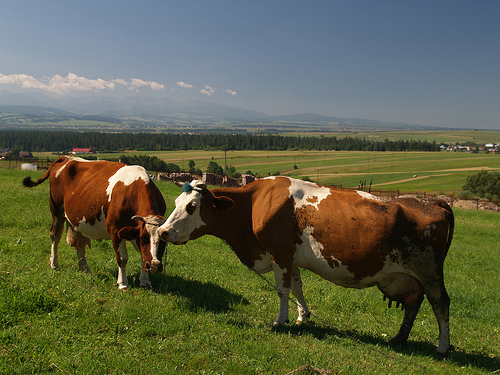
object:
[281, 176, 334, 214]
spots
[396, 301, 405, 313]
udder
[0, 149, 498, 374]
ground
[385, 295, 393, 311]
udder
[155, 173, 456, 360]
cow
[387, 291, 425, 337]
leg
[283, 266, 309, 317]
leg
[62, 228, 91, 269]
leg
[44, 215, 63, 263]
leg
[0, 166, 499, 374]
grass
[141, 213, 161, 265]
streak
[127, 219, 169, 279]
face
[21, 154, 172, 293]
cow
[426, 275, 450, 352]
leg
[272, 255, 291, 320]
leg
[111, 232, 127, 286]
leg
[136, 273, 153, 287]
leg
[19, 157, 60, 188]
tail